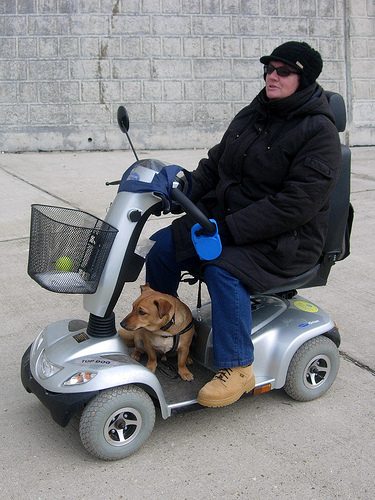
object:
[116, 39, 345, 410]
lady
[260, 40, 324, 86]
hat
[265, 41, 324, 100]
head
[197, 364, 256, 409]
boot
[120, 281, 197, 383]
dog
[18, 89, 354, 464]
scooter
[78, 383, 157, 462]
front tire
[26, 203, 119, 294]
basket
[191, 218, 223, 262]
leash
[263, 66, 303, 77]
sunglasses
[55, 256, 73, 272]
ball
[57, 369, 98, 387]
headlight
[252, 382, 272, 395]
reflector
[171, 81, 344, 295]
jacket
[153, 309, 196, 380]
harness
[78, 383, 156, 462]
wheels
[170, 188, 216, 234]
handlebar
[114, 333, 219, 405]
floor